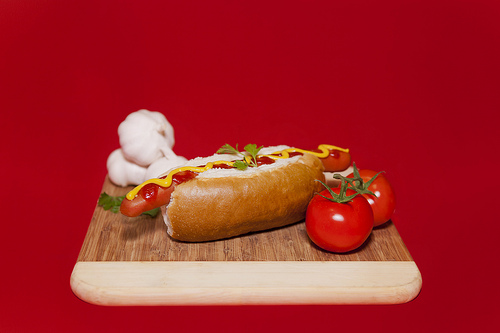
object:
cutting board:
[70, 165, 423, 305]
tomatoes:
[306, 184, 372, 253]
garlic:
[117, 108, 177, 167]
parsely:
[217, 142, 264, 170]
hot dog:
[120, 144, 351, 243]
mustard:
[124, 143, 350, 200]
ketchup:
[141, 148, 340, 203]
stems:
[317, 161, 383, 204]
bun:
[159, 154, 325, 243]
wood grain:
[76, 172, 415, 261]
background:
[1, 0, 500, 332]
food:
[337, 169, 395, 228]